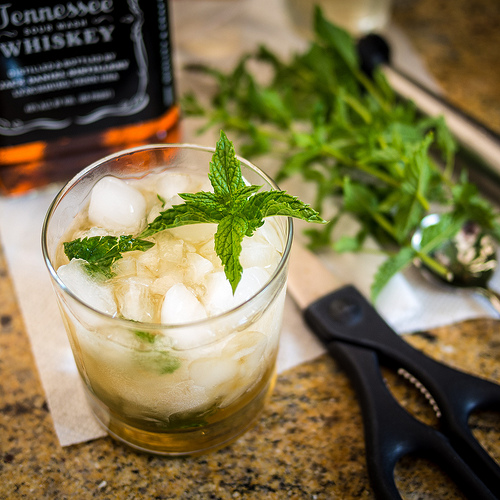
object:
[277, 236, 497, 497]
scissors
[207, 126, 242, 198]
leaf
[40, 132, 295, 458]
glass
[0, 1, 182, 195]
bottle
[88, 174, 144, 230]
ice cube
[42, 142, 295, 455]
drink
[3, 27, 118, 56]
"whiskey"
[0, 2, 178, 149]
label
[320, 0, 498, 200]
spoon